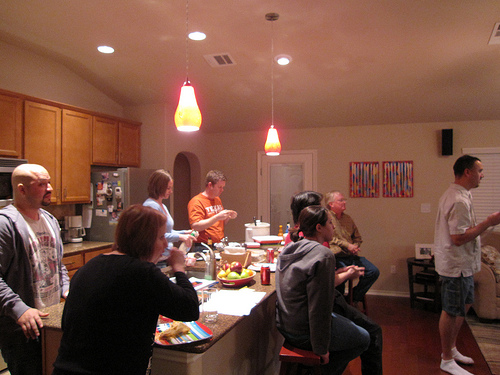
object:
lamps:
[175, 59, 293, 156]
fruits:
[218, 261, 245, 275]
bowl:
[214, 266, 255, 288]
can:
[258, 265, 275, 295]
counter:
[204, 245, 288, 336]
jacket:
[273, 234, 338, 356]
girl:
[269, 200, 335, 367]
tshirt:
[186, 193, 223, 241]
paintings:
[348, 157, 414, 200]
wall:
[322, 131, 422, 153]